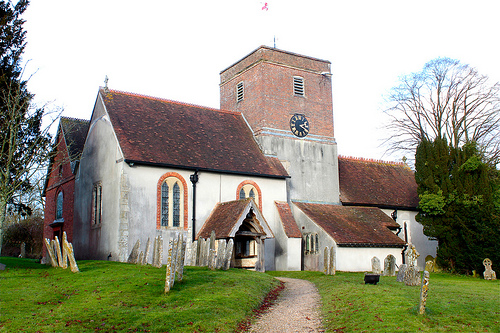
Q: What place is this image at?
A: It is at the church.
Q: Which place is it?
A: It is a church.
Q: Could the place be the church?
A: Yes, it is the church.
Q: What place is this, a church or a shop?
A: It is a church.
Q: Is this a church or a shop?
A: It is a church.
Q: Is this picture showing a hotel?
A: No, the picture is showing a church.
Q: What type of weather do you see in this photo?
A: It is cloudy.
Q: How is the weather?
A: It is cloudy.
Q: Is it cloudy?
A: Yes, it is cloudy.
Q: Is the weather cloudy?
A: Yes, it is cloudy.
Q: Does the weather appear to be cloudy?
A: Yes, it is cloudy.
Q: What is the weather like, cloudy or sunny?
A: It is cloudy.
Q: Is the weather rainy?
A: No, it is cloudy.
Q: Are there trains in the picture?
A: No, there are no trains.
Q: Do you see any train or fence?
A: No, there are no trains or fences.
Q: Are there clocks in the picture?
A: Yes, there is a clock.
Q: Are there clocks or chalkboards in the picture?
A: Yes, there is a clock.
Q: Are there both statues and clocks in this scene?
A: No, there is a clock but no statues.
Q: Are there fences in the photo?
A: No, there are no fences.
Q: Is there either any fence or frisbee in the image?
A: No, there are no fences or frisbees.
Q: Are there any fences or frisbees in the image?
A: No, there are no fences or frisbees.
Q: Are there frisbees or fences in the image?
A: No, there are no fences or frisbees.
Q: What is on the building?
A: The clock is on the building.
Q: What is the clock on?
A: The clock is on the building.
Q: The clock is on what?
A: The clock is on the building.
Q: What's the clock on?
A: The clock is on the building.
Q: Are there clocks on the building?
A: Yes, there is a clock on the building.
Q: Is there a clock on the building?
A: Yes, there is a clock on the building.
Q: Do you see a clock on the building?
A: Yes, there is a clock on the building.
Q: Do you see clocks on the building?
A: Yes, there is a clock on the building.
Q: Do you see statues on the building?
A: No, there is a clock on the building.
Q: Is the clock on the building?
A: Yes, the clock is on the building.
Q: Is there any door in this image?
A: Yes, there is a door.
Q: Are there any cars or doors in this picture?
A: Yes, there is a door.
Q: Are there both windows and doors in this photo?
A: Yes, there are both a door and a window.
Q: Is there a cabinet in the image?
A: No, there are no cabinets.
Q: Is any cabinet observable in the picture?
A: No, there are no cabinets.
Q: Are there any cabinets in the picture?
A: No, there are no cabinets.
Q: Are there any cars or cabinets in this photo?
A: No, there are no cabinets or cars.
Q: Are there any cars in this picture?
A: No, there are no cars.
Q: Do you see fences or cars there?
A: No, there are no cars or fences.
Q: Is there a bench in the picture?
A: No, there are no benches.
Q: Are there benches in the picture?
A: No, there are no benches.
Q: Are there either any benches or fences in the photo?
A: No, there are no benches or fences.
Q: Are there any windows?
A: Yes, there is a window.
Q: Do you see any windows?
A: Yes, there is a window.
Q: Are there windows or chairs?
A: Yes, there is a window.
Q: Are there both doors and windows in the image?
A: Yes, there are both a window and doors.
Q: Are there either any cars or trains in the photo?
A: No, there are no cars or trains.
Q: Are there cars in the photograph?
A: No, there are no cars.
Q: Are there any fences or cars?
A: No, there are no cars or fences.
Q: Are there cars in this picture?
A: No, there are no cars.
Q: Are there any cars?
A: No, there are no cars.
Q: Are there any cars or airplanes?
A: No, there are no cars or airplanes.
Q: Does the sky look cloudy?
A: Yes, the sky is cloudy.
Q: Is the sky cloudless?
A: No, the sky is cloudy.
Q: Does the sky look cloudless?
A: No, the sky is cloudy.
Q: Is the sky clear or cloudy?
A: The sky is cloudy.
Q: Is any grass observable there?
A: Yes, there is grass.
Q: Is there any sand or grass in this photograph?
A: Yes, there is grass.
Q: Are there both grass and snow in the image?
A: No, there is grass but no snow.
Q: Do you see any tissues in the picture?
A: No, there are no tissues.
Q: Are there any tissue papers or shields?
A: No, there are no tissue papers or shields.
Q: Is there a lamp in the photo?
A: No, there are no lamps.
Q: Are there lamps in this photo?
A: No, there are no lamps.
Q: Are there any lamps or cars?
A: No, there are no lamps or cars.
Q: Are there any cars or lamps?
A: No, there are no lamps or cars.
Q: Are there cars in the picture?
A: No, there are no cars.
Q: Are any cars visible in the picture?
A: No, there are no cars.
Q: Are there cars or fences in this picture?
A: No, there are no cars or fences.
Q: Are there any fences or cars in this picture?
A: No, there are no cars or fences.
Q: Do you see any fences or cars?
A: No, there are no cars or fences.